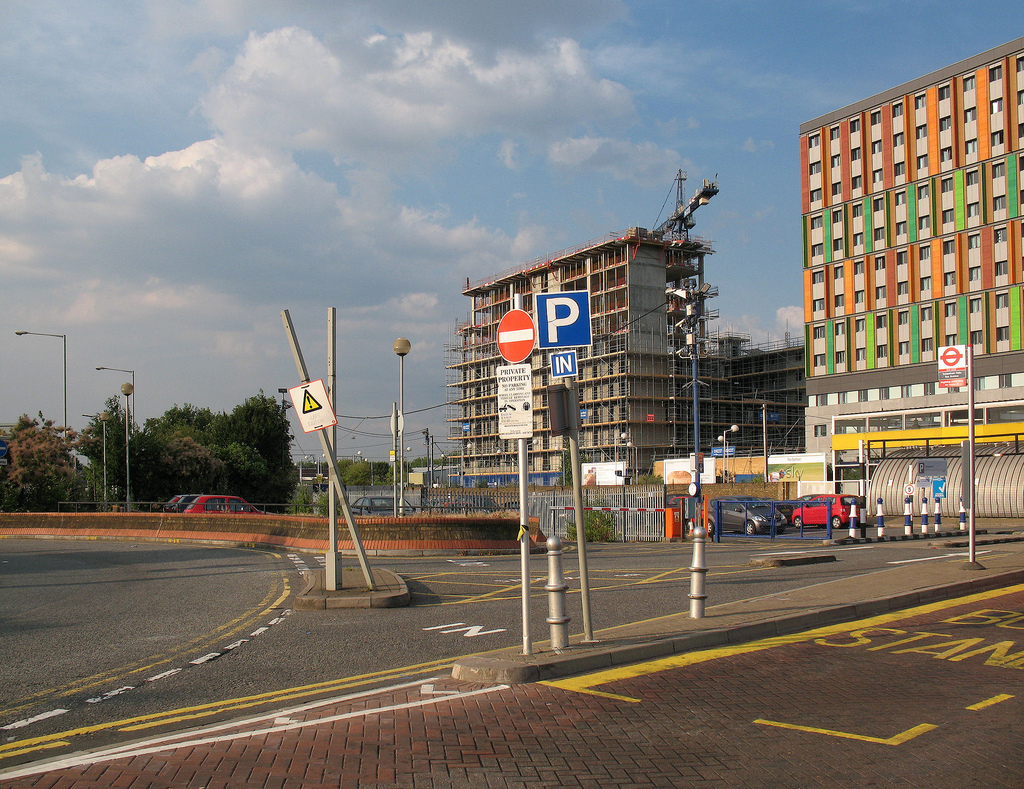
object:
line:
[714, 496, 976, 545]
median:
[406, 548, 1013, 656]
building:
[445, 223, 805, 519]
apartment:
[796, 36, 1024, 452]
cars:
[692, 495, 787, 536]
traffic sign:
[496, 308, 537, 363]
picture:
[0, 0, 1024, 789]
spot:
[535, 579, 1024, 784]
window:
[876, 315, 886, 329]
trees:
[0, 388, 297, 513]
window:
[963, 75, 976, 92]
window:
[967, 201, 979, 218]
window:
[874, 226, 886, 241]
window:
[969, 298, 982, 313]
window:
[814, 353, 826, 368]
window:
[813, 326, 825, 339]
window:
[855, 319, 865, 333]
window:
[856, 347, 867, 361]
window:
[836, 351, 846, 365]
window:
[895, 191, 906, 207]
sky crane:
[652, 167, 720, 240]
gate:
[715, 499, 832, 543]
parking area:
[157, 483, 1011, 544]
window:
[835, 294, 844, 307]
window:
[893, 132, 904, 148]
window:
[877, 344, 887, 358]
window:
[996, 326, 1009, 342]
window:
[964, 106, 977, 123]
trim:
[883, 103, 895, 189]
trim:
[975, 67, 991, 161]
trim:
[840, 119, 853, 203]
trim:
[907, 184, 919, 242]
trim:
[955, 170, 966, 231]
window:
[921, 306, 932, 321]